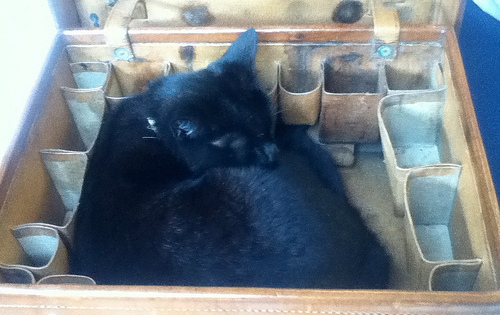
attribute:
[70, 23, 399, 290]
cat — black, curled up, sleeping, large, comfortable, shiny, laying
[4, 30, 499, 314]
container — brown, open, old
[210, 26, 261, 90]
ear — pointy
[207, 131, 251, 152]
eye — closed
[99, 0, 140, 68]
hinge — leather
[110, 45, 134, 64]
attachment — metal